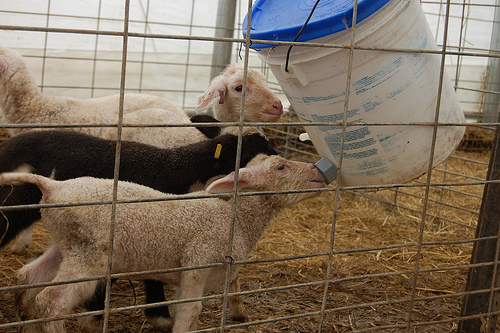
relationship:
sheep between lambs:
[0, 113, 281, 252] [0, 154, 326, 333]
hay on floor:
[280, 209, 448, 290] [1, 152, 499, 332]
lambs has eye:
[0, 154, 326, 333] [275, 163, 286, 173]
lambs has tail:
[0, 154, 326, 333] [0, 170, 52, 192]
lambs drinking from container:
[0, 154, 326, 333] [242, 1, 467, 198]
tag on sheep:
[213, 142, 224, 160] [0, 113, 281, 252]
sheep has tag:
[0, 113, 281, 252] [213, 142, 224, 160]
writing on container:
[289, 38, 427, 180] [242, 1, 467, 198]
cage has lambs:
[0, 1, 500, 331] [0, 46, 326, 333]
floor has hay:
[1, 152, 499, 332] [280, 209, 448, 290]